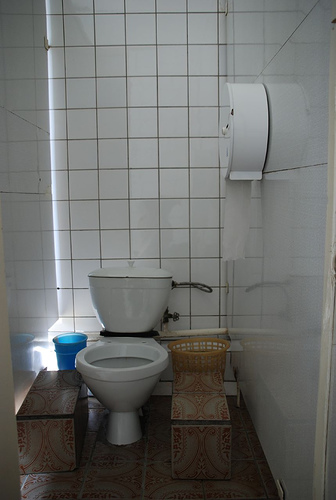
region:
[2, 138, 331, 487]
a bathroom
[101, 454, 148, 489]
tile under the toilet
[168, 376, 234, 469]
a brown shelf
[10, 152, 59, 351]
the white wall of the stall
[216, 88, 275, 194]
a white toilet paper holder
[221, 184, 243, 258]
toilet paper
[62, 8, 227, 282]
white tile on the wall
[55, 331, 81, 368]
a blue bucket next to the toilet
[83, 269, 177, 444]
a white toilet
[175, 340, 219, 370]
a tan basket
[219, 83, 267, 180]
a toilet paper dispenser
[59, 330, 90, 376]
a blue bucket on the ground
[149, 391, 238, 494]
brown tile on the ground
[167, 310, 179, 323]
a knob on the pipe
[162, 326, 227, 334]
a white pipe going to the toilet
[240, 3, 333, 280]
a white stall of the bathroom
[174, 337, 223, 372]
a tan basket on the floor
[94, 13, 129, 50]
white tile on wall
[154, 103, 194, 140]
white tile on wall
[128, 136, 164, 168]
white tile on wall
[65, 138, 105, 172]
white tile on wall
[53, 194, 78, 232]
white tile on wall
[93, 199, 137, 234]
white tile on wall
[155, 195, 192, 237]
white tile on wall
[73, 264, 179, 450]
white ceramic toilet bowl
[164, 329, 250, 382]
yellow wastebasket next to toilet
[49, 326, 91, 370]
blue bucket next to toilet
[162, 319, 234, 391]
this is a dust bin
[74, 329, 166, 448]
this is a toilet bowl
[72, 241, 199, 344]
this is a toilet cistern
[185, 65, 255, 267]
this is a tissue paper holder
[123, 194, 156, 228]
this is a tile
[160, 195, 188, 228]
this is a tile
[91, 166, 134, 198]
this is a tile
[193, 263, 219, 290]
this is a tile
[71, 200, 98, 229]
this is a tile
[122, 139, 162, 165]
this is a tile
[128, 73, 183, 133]
Tiles in the photo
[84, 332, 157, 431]
Toilet seat in the bathroom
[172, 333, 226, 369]
A trash container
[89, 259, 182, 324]
Toilet tank in the photo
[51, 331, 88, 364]
A blue bucket on the corner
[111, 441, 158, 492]
Floor with tiles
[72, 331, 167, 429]
A white toilet seat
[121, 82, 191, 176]
A wall in the bathroom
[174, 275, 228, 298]
A pipe in the bathroom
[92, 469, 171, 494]
Floor in the bathroom